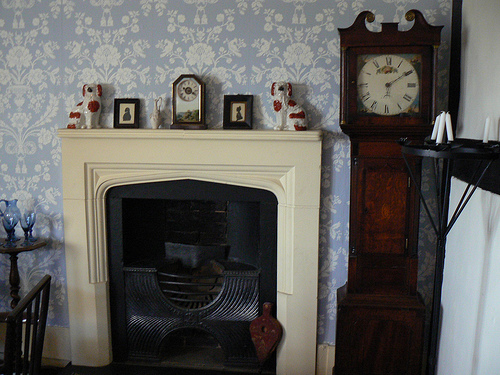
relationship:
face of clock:
[356, 53, 419, 112] [335, 5, 443, 374]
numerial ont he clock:
[382, 52, 394, 69] [335, 5, 443, 374]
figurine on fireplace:
[270, 81, 309, 133] [57, 133, 318, 375]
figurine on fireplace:
[61, 80, 104, 129] [57, 133, 318, 375]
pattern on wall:
[1, 0, 61, 110] [1, 0, 340, 127]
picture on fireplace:
[112, 99, 139, 127] [57, 133, 318, 375]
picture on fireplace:
[225, 95, 252, 128] [57, 133, 318, 375]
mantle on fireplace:
[56, 130, 321, 143] [57, 133, 318, 375]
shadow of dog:
[296, 84, 320, 128] [270, 81, 309, 133]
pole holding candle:
[423, 154, 465, 375] [444, 112, 455, 143]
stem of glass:
[23, 230, 30, 242] [18, 213, 37, 241]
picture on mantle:
[112, 99, 139, 127] [56, 130, 321, 143]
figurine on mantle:
[270, 81, 309, 133] [56, 130, 321, 143]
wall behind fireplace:
[1, 0, 340, 127] [57, 133, 318, 375]